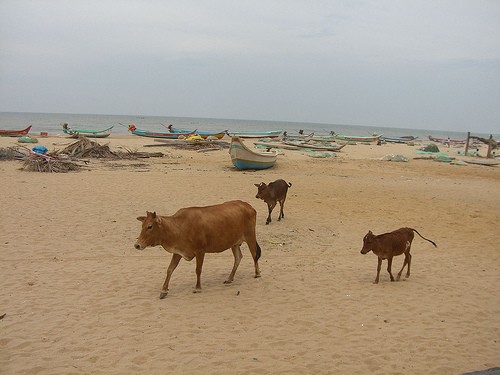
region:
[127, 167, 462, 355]
three cows walking on a beach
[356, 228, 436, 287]
a baby calf walking on a beach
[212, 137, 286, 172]
blue and white boat on the beach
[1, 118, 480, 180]
several boats on the beach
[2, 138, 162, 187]
piles of tree limbs on a beach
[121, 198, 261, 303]
a brown cow walking on a beach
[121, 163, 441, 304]
three brown cows walking on a beach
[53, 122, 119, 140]
a green and white boat on a beach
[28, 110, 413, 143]
the ocean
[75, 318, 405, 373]
tracks in the sand on a beach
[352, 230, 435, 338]
Small cow walking on sand.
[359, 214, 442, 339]
Small cow is brown and white.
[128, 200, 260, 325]
Large brown cow walking on sand.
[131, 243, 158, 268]
Cow has tan nose.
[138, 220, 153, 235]
Cow has dark eye.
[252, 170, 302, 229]
Small cow walking on beach.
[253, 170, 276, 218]
White spot on cow's head.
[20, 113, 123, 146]
Green and white canoe on beach.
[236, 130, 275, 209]
White and blue canoe on beach.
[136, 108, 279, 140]
Water in the distance.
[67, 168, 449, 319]
cows walking beach sand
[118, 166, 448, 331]
some cows walking beach sand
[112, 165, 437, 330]
multiple cows walking beach sand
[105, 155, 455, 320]
few cows walking beach sand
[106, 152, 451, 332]
brown cows walking beach sand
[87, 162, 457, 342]
cows walking beach sand in daylight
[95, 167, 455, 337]
healthy cows walking beach sand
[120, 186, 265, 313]
adult cow on sand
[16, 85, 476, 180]
boats near sea shore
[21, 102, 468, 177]
multiple boats along sea shore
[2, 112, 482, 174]
Boats are on the sand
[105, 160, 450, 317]
Three animals walking on the beach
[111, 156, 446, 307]
Animals are brown in color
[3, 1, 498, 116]
The sky is cloudy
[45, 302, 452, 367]
Tracks are in the sand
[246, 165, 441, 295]
Two young animals are the beach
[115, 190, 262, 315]
One adult animal is on the beach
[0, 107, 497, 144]
An ocean is in the background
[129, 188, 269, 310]
A side view of an animal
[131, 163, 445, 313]
Animals in this picture are cows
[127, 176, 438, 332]
cows walking on sand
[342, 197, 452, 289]
brown calf walking on sand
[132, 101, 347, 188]
boats along the shoreline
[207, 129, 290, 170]
blue and white boat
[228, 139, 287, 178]
red stripe on boat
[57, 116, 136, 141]
turquoise and white boat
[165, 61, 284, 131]
water and gray-blue sky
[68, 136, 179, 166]
pile of wood on beach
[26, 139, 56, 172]
blue object by wood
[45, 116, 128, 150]
motor on back of boat